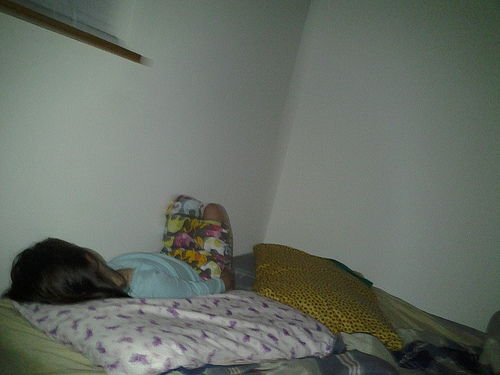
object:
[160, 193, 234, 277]
flowery pants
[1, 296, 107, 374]
sheets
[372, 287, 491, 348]
sheets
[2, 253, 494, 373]
bed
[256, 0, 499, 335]
wall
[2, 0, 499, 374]
room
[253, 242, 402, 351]
pillow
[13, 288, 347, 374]
pillow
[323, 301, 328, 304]
dots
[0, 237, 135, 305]
hair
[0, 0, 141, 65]
shelf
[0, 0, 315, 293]
wall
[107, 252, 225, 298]
t-shirt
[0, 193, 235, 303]
kid